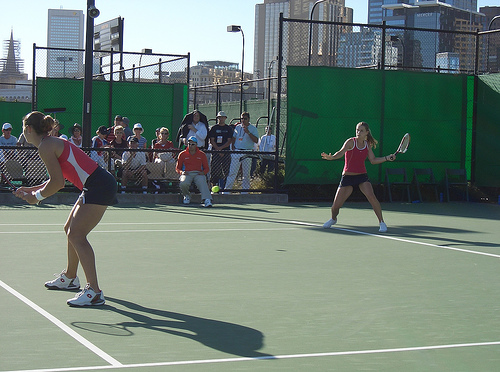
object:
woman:
[0, 120, 20, 163]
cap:
[1, 122, 14, 131]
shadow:
[66, 292, 283, 362]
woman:
[127, 122, 151, 163]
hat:
[132, 122, 144, 134]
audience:
[0, 109, 282, 209]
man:
[175, 136, 214, 208]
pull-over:
[174, 146, 209, 175]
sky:
[0, 0, 500, 90]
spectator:
[153, 126, 174, 161]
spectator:
[119, 136, 149, 192]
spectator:
[127, 121, 147, 148]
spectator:
[110, 126, 130, 153]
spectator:
[99, 147, 114, 176]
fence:
[0, 145, 278, 193]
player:
[319, 119, 400, 234]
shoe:
[378, 222, 388, 233]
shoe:
[322, 218, 337, 229]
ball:
[211, 185, 220, 193]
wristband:
[34, 189, 47, 201]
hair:
[21, 110, 55, 136]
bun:
[39, 114, 56, 133]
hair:
[354, 121, 378, 150]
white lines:
[292, 220, 500, 259]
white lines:
[1, 340, 500, 372]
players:
[11, 108, 121, 308]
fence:
[271, 10, 500, 189]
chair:
[444, 167, 470, 203]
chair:
[412, 167, 440, 204]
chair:
[382, 167, 411, 204]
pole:
[226, 24, 245, 121]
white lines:
[0, 278, 124, 366]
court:
[0, 201, 499, 372]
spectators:
[3, 106, 280, 181]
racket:
[390, 132, 411, 160]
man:
[179, 109, 208, 150]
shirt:
[180, 120, 207, 148]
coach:
[174, 135, 213, 208]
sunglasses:
[187, 140, 194, 146]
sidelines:
[0, 145, 37, 150]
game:
[0, 103, 415, 311]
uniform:
[337, 137, 373, 187]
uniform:
[55, 135, 119, 207]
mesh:
[285, 65, 476, 185]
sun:
[302, 261, 465, 332]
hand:
[386, 153, 396, 161]